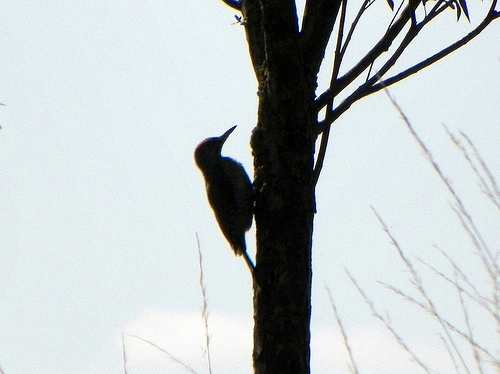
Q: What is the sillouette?
A: Tree and bird.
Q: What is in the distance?
A: Branches.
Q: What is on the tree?
A: A bird.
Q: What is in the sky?
A: Clouds.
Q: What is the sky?
A: Blue.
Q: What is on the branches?
A: Leaves.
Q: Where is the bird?
A: On the tree.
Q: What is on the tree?
A: Bird.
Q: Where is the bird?
A: On a tree.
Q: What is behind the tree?
A: Grass.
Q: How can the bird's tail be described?
A: Long.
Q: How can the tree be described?
A: Bare.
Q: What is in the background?
A: Sky.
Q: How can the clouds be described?
A: Puffy.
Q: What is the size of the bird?
A: Small.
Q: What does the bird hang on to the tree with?
A: Talons.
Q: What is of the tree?
A: Branches.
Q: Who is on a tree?
A: A bird.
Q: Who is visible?
A: A bird.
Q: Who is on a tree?
A: A bird.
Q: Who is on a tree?
A: A bird.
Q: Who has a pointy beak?
A: The bird.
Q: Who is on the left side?
A: The bird.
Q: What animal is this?
A: A bird.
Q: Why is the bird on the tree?
A: It is resting.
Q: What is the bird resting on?
A: The tree.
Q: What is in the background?
A: Branches.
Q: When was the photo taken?
A: Daytime.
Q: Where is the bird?
A: On the tree.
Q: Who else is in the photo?
A: Nobody.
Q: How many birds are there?
A: One.